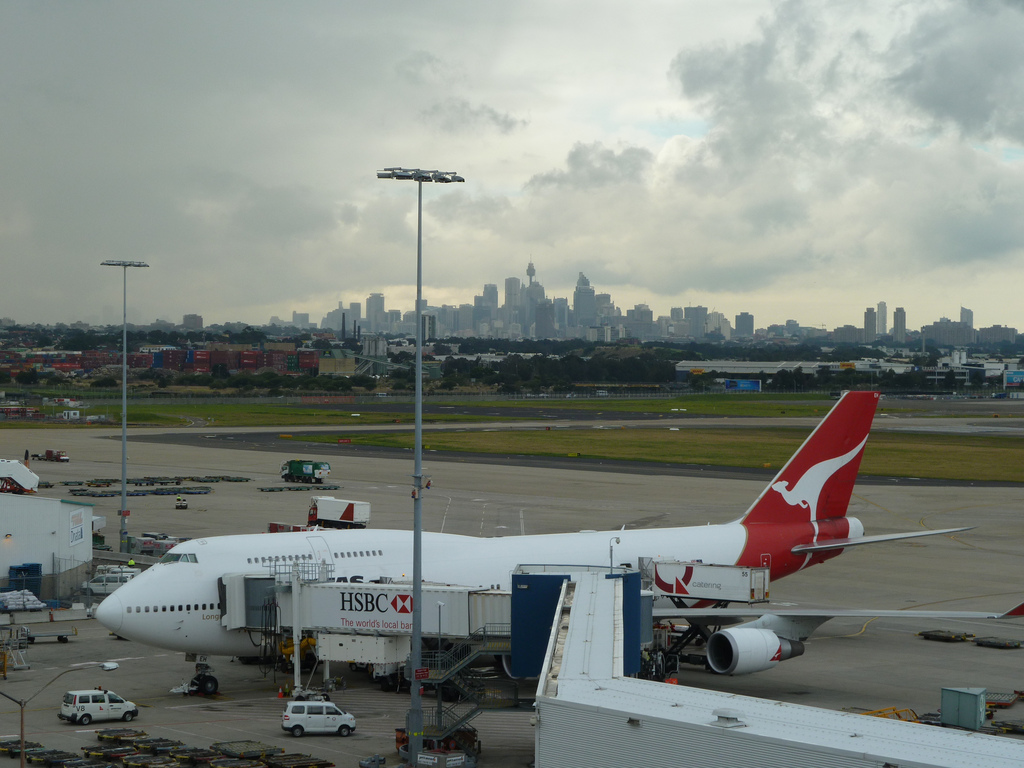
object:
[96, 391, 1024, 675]
airplane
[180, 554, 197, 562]
window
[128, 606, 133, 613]
window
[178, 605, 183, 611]
window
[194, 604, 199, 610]
window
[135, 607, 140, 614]
window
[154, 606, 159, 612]
window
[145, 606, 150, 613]
window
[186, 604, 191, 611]
window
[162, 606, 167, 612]
window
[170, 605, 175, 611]
window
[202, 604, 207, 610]
window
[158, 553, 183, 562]
window